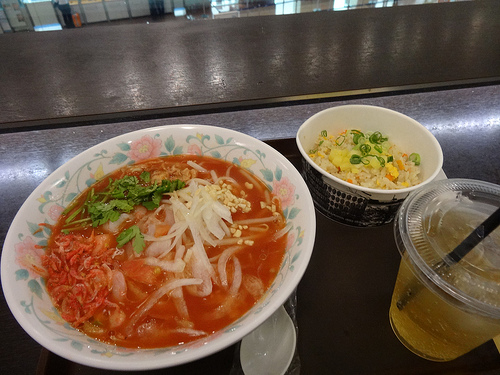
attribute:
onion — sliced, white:
[126, 276, 203, 337]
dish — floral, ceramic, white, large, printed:
[3, 116, 322, 374]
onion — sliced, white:
[215, 245, 247, 287]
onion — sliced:
[159, 324, 208, 341]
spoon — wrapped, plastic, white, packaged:
[235, 301, 299, 374]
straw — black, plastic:
[396, 202, 500, 316]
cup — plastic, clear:
[385, 178, 499, 361]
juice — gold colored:
[386, 206, 499, 366]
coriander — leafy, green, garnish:
[61, 170, 189, 256]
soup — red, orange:
[40, 154, 289, 355]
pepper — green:
[349, 154, 363, 167]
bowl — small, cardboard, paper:
[291, 104, 448, 232]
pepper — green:
[319, 127, 330, 141]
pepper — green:
[369, 128, 389, 147]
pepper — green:
[408, 148, 421, 167]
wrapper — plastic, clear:
[222, 282, 306, 374]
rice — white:
[310, 127, 426, 192]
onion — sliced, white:
[142, 228, 188, 245]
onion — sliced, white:
[169, 192, 219, 292]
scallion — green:
[358, 143, 374, 157]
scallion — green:
[385, 156, 396, 165]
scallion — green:
[350, 126, 367, 146]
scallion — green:
[316, 140, 327, 150]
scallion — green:
[374, 153, 386, 170]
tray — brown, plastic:
[33, 132, 498, 374]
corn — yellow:
[332, 154, 342, 165]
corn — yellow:
[328, 147, 342, 160]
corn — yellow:
[338, 162, 352, 175]